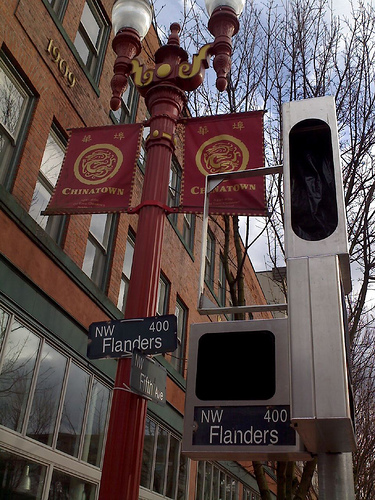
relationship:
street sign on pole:
[87, 314, 178, 361] [99, 4, 239, 499]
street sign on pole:
[128, 348, 166, 405] [99, 4, 239, 499]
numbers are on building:
[45, 36, 76, 88] [1, 1, 318, 500]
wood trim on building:
[1, 0, 318, 499] [1, 1, 318, 500]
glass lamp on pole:
[111, 1, 154, 42] [99, 4, 239, 499]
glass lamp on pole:
[204, 0, 247, 17] [99, 4, 239, 499]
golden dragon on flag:
[81, 148, 116, 180] [40, 122, 143, 216]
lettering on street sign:
[95, 325, 162, 352] [87, 314, 178, 361]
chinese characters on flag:
[82, 130, 126, 144] [40, 122, 143, 216]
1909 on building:
[45, 36, 76, 88] [1, 1, 318, 500]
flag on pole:
[172, 110, 273, 217] [99, 4, 239, 499]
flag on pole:
[40, 122, 143, 216] [99, 4, 239, 499]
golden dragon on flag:
[202, 141, 242, 175] [172, 110, 273, 217]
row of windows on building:
[0, 301, 261, 499] [1, 1, 318, 500]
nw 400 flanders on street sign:
[95, 319, 169, 352] [87, 314, 178, 361]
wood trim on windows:
[1, 0, 318, 499] [0, 1, 319, 500]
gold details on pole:
[128, 43, 209, 139] [99, 4, 239, 499]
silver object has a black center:
[281, 96, 348, 257] [289, 118, 338, 240]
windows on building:
[0, 1, 319, 500] [1, 1, 318, 500]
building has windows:
[1, 1, 318, 500] [0, 1, 319, 500]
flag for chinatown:
[172, 110, 273, 217] [190, 183, 256, 195]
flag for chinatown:
[40, 122, 143, 216] [62, 187, 125, 195]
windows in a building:
[0, 1, 319, 500] [1, 1, 318, 500]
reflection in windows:
[1, 58, 262, 499] [0, 1, 319, 500]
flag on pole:
[172, 110, 273, 217] [98, 22, 189, 499]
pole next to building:
[99, 4, 239, 499] [1, 1, 318, 500]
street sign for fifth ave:
[128, 348, 166, 405] [139, 372, 164, 399]